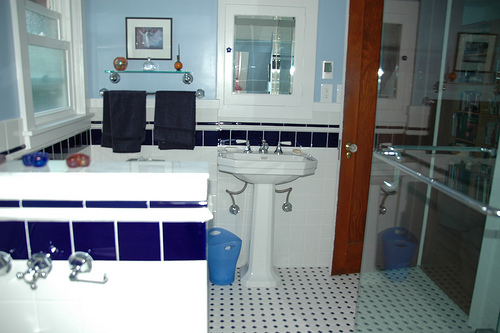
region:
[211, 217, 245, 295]
blue trash can on bathroom floor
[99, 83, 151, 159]
dark towel on towel rack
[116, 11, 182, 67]
picture on bathroom wall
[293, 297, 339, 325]
grey and white tile on bathroom floor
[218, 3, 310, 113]
mirror above bathroom sink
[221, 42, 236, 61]
knob on medicine cabinet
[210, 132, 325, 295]
white pedestal sink in bathroom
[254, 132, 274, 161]
silver faucet on bathroom sink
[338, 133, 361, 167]
door handle on wooden door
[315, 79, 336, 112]
power outlet on bathroom wall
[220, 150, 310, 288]
white pedestal bathroom sink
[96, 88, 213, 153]
dark blue towels hanging from towel rack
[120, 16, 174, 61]
small picture with frame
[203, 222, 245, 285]
small blue wastepaper basket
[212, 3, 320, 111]
built in medicine cabinet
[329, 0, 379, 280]
edge of a brown wooden door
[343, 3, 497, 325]
reflection of bathroom objects in shower door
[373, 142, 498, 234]
long chrome colored handle on shower door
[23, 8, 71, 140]
window in wall with white frame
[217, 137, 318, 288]
A white pedestal sink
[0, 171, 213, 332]
A white and blue tiled wall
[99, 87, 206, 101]
A hanging towel rack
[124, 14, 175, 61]
A framed piece of art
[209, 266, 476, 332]
A black and white tiled floor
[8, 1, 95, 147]
A white framed window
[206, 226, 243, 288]
A blue plastic trash can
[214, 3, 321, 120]
A white medicine cabinet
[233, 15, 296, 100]
A cabinet mirror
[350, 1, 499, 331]
A glass showe enclosure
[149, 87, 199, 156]
a black towel on a rack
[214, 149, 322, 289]
a white pedestal sink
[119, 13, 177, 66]
a framed picture above a towel rack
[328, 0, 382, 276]
a wooden bathroom door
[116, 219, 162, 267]
a blue tile in a bathroom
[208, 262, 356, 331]
a white and black tiled floor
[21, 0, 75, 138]
a white framed bathroom window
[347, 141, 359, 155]
a doorknob on a bathroom door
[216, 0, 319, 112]
a white medicine cabinet above a sink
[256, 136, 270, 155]
the faucet on a bathroom sink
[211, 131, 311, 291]
a sink in the bathroom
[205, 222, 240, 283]
a blue basket in the bathroom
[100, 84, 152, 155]
a blue towel on a rack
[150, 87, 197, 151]
a blue towel on a rack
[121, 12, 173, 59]
a painting on a wall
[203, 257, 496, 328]
a bathroom floor with white and blue pattern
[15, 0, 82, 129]
a window in the bathroom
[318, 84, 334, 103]
an power plug in a bathroom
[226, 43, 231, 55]
the handle to a bathroom cabinet